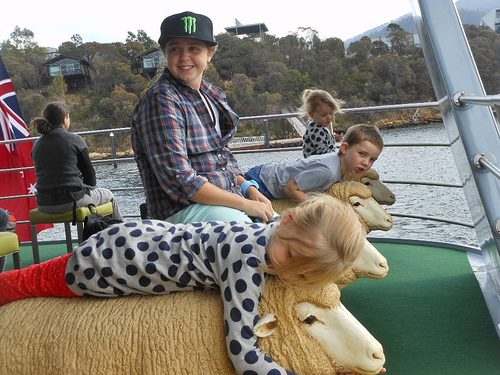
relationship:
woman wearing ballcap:
[129, 12, 281, 225] [157, 11, 217, 47]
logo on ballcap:
[181, 12, 201, 34] [157, 11, 217, 47]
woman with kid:
[128, 13, 281, 219] [301, 80, 339, 158]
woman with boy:
[128, 13, 281, 219] [241, 123, 384, 204]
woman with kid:
[128, 13, 281, 219] [1, 199, 367, 371]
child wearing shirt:
[0, 195, 387, 374] [78, 198, 353, 368]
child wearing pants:
[0, 195, 387, 374] [0, 250, 83, 305]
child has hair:
[0, 195, 387, 374] [249, 192, 369, 294]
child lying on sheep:
[0, 195, 387, 374] [0, 281, 386, 373]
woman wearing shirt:
[129, 12, 281, 225] [139, 72, 249, 202]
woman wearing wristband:
[129, 12, 281, 225] [240, 176, 257, 192]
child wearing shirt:
[0, 195, 387, 374] [59, 218, 288, 373]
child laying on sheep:
[0, 196, 368, 373] [0, 285, 385, 372]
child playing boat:
[0, 195, 387, 374] [5, 8, 482, 373]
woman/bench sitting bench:
[32, 101, 124, 221] [30, 201, 117, 265]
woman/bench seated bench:
[28, 101, 115, 221] [24, 207, 101, 248]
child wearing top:
[0, 195, 387, 374] [85, 211, 297, 372]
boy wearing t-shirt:
[243, 120, 396, 197] [273, 157, 337, 178]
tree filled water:
[311, 35, 343, 62] [382, 126, 497, 246]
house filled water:
[54, 51, 88, 91] [382, 126, 497, 246]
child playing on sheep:
[0, 195, 387, 374] [5, 235, 389, 374]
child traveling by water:
[0, 195, 387, 374] [407, 121, 446, 241]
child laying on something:
[0, 195, 387, 374] [3, 296, 235, 365]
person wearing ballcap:
[130, 6, 276, 228] [157, 11, 217, 47]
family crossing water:
[1, 10, 385, 374] [383, 126, 466, 240]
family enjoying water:
[1, 10, 385, 374] [39, 119, 499, 241]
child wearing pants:
[0, 195, 387, 374] [0, 242, 82, 305]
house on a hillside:
[42, 53, 92, 93] [24, 41, 198, 137]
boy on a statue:
[241, 123, 384, 204] [264, 180, 387, 227]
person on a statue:
[130, 10, 276, 225] [347, 233, 381, 294]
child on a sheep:
[0, 196, 368, 373] [0, 281, 386, 373]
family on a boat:
[1, 10, 385, 374] [5, 8, 482, 373]